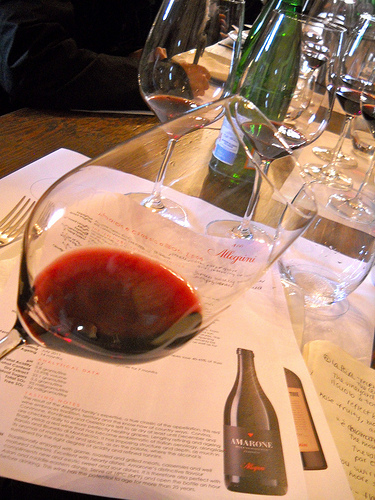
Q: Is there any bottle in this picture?
A: Yes, there is a bottle.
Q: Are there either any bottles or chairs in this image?
A: Yes, there is a bottle.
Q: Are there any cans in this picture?
A: No, there are no cans.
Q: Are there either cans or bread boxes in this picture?
A: No, there are no cans or bread boxes.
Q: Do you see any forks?
A: Yes, there is a fork.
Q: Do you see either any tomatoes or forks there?
A: Yes, there is a fork.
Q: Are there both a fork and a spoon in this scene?
A: No, there is a fork but no spoons.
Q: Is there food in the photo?
A: No, there is no food.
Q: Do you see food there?
A: No, there is no food.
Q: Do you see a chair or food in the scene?
A: No, there are no food or chairs.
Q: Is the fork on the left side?
A: Yes, the fork is on the left of the image.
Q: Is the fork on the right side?
A: No, the fork is on the left of the image.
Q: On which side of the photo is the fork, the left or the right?
A: The fork is on the left of the image.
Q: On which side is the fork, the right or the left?
A: The fork is on the left of the image.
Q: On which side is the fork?
A: The fork is on the left of the image.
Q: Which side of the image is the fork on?
A: The fork is on the left of the image.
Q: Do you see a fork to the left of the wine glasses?
A: Yes, there is a fork to the left of the wine glasses.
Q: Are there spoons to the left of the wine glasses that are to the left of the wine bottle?
A: No, there is a fork to the left of the wine glasses.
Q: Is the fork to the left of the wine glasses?
A: Yes, the fork is to the left of the wine glasses.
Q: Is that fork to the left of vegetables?
A: No, the fork is to the left of the wine glasses.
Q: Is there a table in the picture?
A: Yes, there is a table.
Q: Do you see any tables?
A: Yes, there is a table.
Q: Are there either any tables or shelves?
A: Yes, there is a table.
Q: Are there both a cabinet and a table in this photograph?
A: No, there is a table but no cabinets.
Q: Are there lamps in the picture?
A: No, there are no lamps.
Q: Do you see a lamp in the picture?
A: No, there are no lamps.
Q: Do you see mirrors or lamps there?
A: No, there are no lamps or mirrors.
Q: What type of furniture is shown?
A: The furniture is a table.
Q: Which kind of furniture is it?
A: The piece of furniture is a table.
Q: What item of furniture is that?
A: This is a table.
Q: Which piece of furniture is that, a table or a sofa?
A: This is a table.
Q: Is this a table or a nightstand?
A: This is a table.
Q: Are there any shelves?
A: No, there are no shelves.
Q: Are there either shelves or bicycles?
A: No, there are no shelves or bicycles.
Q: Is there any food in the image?
A: No, there is no food.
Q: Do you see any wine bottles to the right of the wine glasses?
A: Yes, there is a wine bottle to the right of the wine glasses.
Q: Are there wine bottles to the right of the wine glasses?
A: Yes, there is a wine bottle to the right of the wine glasses.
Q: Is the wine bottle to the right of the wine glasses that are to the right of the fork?
A: Yes, the wine bottle is to the right of the wine glasses.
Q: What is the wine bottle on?
A: The wine bottle is on the table.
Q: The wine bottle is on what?
A: The wine bottle is on the table.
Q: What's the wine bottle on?
A: The wine bottle is on the table.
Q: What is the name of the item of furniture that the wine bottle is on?
A: The piece of furniture is a table.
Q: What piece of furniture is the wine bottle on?
A: The wine bottle is on the table.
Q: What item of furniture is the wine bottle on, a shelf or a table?
A: The wine bottle is on a table.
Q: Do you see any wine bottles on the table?
A: Yes, there is a wine bottle on the table.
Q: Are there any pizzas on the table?
A: No, there is a wine bottle on the table.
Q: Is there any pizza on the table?
A: No, there is a wine bottle on the table.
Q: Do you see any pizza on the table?
A: No, there is a wine bottle on the table.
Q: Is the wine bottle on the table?
A: Yes, the wine bottle is on the table.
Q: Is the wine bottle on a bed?
A: No, the wine bottle is on the table.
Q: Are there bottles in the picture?
A: Yes, there is a bottle.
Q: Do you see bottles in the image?
A: Yes, there is a bottle.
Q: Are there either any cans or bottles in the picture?
A: Yes, there is a bottle.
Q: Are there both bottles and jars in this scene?
A: No, there is a bottle but no jars.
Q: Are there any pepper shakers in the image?
A: No, there are no pepper shakers.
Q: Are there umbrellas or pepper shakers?
A: No, there are no pepper shakers or umbrellas.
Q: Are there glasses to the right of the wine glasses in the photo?
A: Yes, there are glasses to the right of the wine glasses.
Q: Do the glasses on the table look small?
A: Yes, the glasses are small.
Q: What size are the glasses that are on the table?
A: The glasses are small.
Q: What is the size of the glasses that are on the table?
A: The glasses are small.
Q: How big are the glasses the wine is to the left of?
A: The glasses are small.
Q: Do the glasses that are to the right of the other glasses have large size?
A: No, the glasses are small.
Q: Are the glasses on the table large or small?
A: The glasses are small.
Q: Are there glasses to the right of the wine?
A: Yes, there are glasses to the right of the wine.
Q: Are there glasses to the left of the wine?
A: No, the glasses are to the right of the wine.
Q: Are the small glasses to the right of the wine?
A: Yes, the glasses are to the right of the wine.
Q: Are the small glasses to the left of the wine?
A: No, the glasses are to the right of the wine.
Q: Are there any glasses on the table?
A: Yes, there are glasses on the table.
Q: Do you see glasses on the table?
A: Yes, there are glasses on the table.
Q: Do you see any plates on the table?
A: No, there are glasses on the table.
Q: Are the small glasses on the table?
A: Yes, the glasses are on the table.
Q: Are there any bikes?
A: No, there are no bikes.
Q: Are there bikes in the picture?
A: No, there are no bikes.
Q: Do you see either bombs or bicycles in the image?
A: No, there are no bicycles or bombs.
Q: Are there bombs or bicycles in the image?
A: No, there are no bicycles or bombs.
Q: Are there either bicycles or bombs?
A: No, there are no bicycles or bombs.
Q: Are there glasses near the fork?
A: Yes, there are glasses near the fork.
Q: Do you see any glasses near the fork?
A: Yes, there are glasses near the fork.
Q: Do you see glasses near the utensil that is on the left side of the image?
A: Yes, there are glasses near the fork.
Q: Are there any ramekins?
A: No, there are no ramekins.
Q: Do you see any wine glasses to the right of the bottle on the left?
A: Yes, there are wine glasses to the right of the bottle.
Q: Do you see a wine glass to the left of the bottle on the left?
A: No, the wine glasses are to the right of the bottle.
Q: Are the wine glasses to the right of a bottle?
A: Yes, the wine glasses are to the right of a bottle.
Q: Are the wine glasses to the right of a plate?
A: No, the wine glasses are to the right of a bottle.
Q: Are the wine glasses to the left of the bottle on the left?
A: No, the wine glasses are to the right of the bottle.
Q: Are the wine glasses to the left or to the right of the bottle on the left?
A: The wine glasses are to the right of the bottle.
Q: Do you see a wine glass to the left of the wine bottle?
A: Yes, there are wine glasses to the left of the wine bottle.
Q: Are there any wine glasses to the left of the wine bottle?
A: Yes, there are wine glasses to the left of the wine bottle.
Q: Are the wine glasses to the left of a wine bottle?
A: Yes, the wine glasses are to the left of a wine bottle.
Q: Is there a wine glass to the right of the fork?
A: Yes, there are wine glasses to the right of the fork.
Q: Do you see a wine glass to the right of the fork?
A: Yes, there are wine glasses to the right of the fork.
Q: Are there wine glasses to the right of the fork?
A: Yes, there are wine glasses to the right of the fork.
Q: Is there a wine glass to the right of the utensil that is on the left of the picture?
A: Yes, there are wine glasses to the right of the fork.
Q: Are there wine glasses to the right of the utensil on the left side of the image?
A: Yes, there are wine glasses to the right of the fork.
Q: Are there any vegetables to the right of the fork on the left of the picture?
A: No, there are wine glasses to the right of the fork.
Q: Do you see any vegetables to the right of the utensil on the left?
A: No, there are wine glasses to the right of the fork.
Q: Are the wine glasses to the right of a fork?
A: Yes, the wine glasses are to the right of a fork.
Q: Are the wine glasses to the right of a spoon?
A: No, the wine glasses are to the right of a fork.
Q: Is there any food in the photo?
A: No, there is no food.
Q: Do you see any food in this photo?
A: No, there is no food.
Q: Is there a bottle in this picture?
A: Yes, there is a bottle.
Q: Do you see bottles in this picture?
A: Yes, there is a bottle.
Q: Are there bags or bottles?
A: Yes, there is a bottle.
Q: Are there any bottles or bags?
A: Yes, there is a bottle.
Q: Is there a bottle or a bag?
A: Yes, there is a bottle.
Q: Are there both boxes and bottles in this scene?
A: No, there is a bottle but no boxes.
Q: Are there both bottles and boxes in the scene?
A: No, there is a bottle but no boxes.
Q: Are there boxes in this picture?
A: No, there are no boxes.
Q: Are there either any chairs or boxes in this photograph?
A: No, there are no boxes or chairs.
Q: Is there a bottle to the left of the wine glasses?
A: Yes, there is a bottle to the left of the wine glasses.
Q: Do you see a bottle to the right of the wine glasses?
A: No, the bottle is to the left of the wine glasses.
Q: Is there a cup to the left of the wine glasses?
A: No, there is a bottle to the left of the wine glasses.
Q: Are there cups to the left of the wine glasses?
A: No, there is a bottle to the left of the wine glasses.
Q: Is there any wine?
A: Yes, there is wine.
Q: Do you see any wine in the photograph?
A: Yes, there is wine.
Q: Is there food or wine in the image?
A: Yes, there is wine.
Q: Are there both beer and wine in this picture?
A: No, there is wine but no beer.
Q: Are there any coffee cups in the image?
A: No, there are no coffee cups.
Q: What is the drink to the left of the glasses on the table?
A: The drink is wine.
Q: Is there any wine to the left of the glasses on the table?
A: Yes, there is wine to the left of the glasses.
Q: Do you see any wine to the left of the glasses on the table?
A: Yes, there is wine to the left of the glasses.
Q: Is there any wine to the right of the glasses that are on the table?
A: No, the wine is to the left of the glasses.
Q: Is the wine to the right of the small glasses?
A: No, the wine is to the left of the glasses.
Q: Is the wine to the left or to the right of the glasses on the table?
A: The wine is to the left of the glasses.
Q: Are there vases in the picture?
A: No, there are no vases.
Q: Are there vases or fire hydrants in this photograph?
A: No, there are no vases or fire hydrants.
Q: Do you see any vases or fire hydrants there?
A: No, there are no vases or fire hydrants.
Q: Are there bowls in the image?
A: No, there are no bowls.